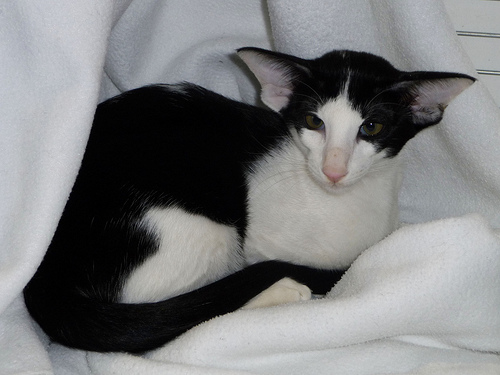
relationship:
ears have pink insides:
[236, 37, 468, 136] [246, 49, 459, 117]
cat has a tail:
[31, 18, 469, 342] [63, 250, 333, 348]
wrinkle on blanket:
[299, 317, 485, 374] [159, 210, 500, 368]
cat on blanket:
[31, 18, 469, 342] [159, 210, 500, 368]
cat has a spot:
[31, 18, 469, 342] [159, 75, 193, 101]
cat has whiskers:
[31, 18, 469, 342] [241, 137, 322, 224]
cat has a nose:
[31, 18, 469, 342] [315, 159, 358, 188]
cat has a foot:
[31, 18, 469, 342] [263, 275, 312, 314]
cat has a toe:
[31, 18, 469, 342] [272, 261, 318, 305]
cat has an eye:
[31, 18, 469, 342] [354, 111, 393, 146]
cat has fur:
[31, 18, 469, 342] [259, 157, 316, 265]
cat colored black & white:
[31, 18, 469, 342] [205, 148, 292, 232]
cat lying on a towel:
[31, 18, 469, 342] [309, 220, 499, 343]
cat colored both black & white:
[31, 18, 469, 342] [205, 148, 292, 232]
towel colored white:
[309, 220, 499, 343] [390, 281, 459, 322]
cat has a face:
[31, 18, 469, 342] [286, 85, 396, 199]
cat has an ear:
[31, 18, 469, 342] [235, 38, 320, 111]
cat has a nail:
[31, 18, 469, 342] [306, 279, 318, 295]